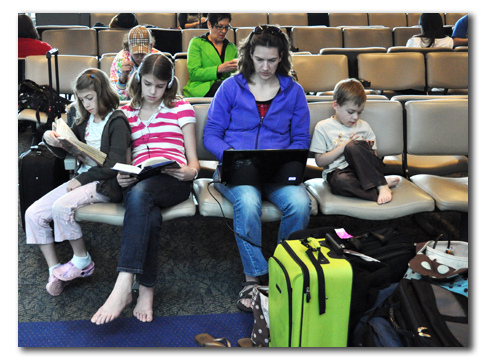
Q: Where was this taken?
A: An airport.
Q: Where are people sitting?
A: On chairs.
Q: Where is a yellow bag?
A: On the floor.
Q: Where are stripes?
A: On girl's shirt.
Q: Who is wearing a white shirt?
A: Boy on the right.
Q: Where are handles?
A: On the bags.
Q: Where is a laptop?
A: On woman's lap.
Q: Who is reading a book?
A: Two girls.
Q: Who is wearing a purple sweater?
A: Woman with laptop.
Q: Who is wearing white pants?
A: Girl on left.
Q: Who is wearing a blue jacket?
A: The woman with the laptop computer.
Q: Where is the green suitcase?
A: In front of the woman wearing jeans.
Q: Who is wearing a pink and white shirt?
A: The girl with pigtails.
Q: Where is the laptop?
A: On the woman's lap.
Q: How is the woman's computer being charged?
A: With a power cord.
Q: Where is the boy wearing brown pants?
A: Next to the woman in blue.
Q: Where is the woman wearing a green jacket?
A: Behind the family.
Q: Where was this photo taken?
A: In an airport.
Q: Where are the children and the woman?
A: Sitting in an airport.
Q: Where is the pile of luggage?
A: In front of the camera.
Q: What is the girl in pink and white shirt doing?
A: Reading.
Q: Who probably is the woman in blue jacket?
A: Children's mother.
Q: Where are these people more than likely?
A: At bus terminal.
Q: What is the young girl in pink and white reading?
A: A book.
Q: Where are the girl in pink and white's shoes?
A: On floor.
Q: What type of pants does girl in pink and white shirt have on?
A: Blue jeans.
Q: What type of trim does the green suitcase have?
A: Black.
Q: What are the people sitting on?
A: Bench type seats.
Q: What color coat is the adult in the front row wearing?
A: Blue.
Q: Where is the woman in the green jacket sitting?
A: Two rows behind the woman in the blue coat.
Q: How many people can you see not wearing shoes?
A: Two.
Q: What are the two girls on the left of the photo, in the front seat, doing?
A: Reading books.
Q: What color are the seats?
A: Beige.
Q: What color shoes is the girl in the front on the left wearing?
A: Pink.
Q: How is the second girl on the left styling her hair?
A: In pigtails.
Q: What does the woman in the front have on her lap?
A: A laptop.